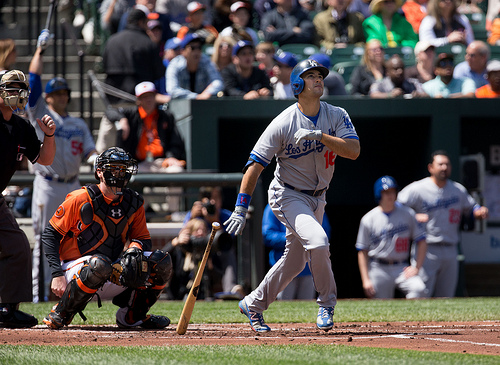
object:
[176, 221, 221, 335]
baseball bat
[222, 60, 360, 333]
batter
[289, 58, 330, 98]
helmet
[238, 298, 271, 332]
shoes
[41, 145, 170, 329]
catcher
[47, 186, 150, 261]
vest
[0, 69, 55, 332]
umpire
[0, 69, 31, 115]
mask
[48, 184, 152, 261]
shirt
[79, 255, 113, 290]
knee pads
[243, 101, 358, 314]
uniform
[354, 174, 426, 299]
player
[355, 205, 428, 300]
uniform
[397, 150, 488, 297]
player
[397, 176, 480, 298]
uniform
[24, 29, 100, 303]
player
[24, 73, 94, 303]
uniform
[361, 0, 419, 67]
woman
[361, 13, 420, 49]
clothes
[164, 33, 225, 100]
audience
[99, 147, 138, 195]
face mask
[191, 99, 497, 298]
dugout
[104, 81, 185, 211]
coach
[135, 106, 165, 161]
shirt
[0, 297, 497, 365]
field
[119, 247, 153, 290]
mitt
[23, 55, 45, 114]
arm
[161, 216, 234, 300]
photographer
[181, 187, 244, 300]
photographer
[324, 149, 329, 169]
number